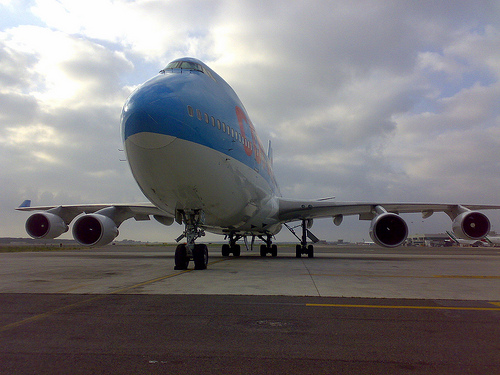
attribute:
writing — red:
[235, 108, 275, 173]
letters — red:
[237, 96, 282, 191]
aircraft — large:
[14, 53, 498, 279]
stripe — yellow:
[303, 299, 498, 312]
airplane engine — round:
[450, 208, 491, 240]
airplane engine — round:
[366, 204, 410, 247]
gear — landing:
[174, 195, 217, 270]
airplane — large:
[14, 47, 499, 300]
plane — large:
[11, 51, 497, 273]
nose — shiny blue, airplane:
[116, 78, 229, 191]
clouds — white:
[5, 4, 498, 238]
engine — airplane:
[445, 208, 493, 243]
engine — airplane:
[365, 208, 412, 247]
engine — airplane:
[68, 213, 121, 245]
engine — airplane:
[22, 210, 68, 241]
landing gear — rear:
[293, 241, 319, 260]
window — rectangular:
[193, 102, 210, 122]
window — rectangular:
[210, 118, 228, 134]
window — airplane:
[181, 59, 205, 72]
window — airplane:
[161, 59, 180, 70]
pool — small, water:
[137, 350, 175, 369]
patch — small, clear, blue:
[0, 2, 44, 28]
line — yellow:
[301, 299, 483, 312]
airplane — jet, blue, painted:
[15, 56, 497, 273]